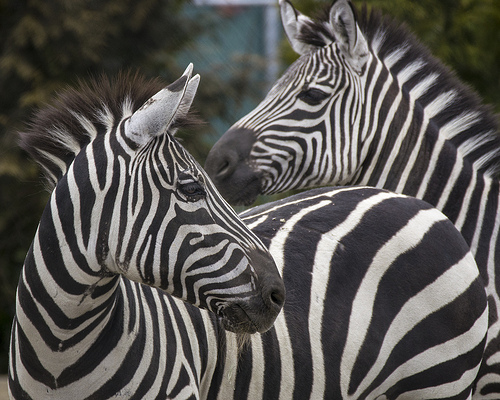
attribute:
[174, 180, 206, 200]
eye — black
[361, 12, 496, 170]
mane — STIFF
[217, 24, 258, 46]
wall — green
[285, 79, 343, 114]
eye — small and dark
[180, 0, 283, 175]
fence — green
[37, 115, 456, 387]
zebra — large, black and white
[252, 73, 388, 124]
dark eye — small and dark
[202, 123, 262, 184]
zebra nose — grey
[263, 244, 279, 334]
nose — black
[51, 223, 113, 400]
stripes — black and white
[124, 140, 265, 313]
stripes — narrow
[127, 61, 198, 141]
ears — white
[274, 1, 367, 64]
ears — white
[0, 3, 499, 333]
trees — green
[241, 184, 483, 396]
stripes — wide